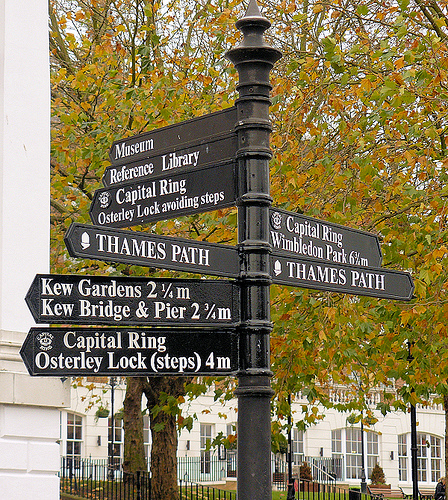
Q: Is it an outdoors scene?
A: Yes, it is outdoors.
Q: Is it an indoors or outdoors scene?
A: It is outdoors.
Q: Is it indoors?
A: No, it is outdoors.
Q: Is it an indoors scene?
A: No, it is outdoors.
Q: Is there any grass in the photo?
A: Yes, there is grass.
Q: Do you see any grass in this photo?
A: Yes, there is grass.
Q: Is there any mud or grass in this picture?
A: Yes, there is grass.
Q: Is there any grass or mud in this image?
A: Yes, there is grass.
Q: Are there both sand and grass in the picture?
A: No, there is grass but no sand.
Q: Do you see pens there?
A: No, there are no pens.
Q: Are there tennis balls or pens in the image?
A: No, there are no pens or tennis balls.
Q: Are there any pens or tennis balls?
A: No, there are no pens or tennis balls.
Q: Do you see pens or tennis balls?
A: No, there are no pens or tennis balls.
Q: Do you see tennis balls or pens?
A: No, there are no pens or tennis balls.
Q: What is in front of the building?
A: The grass is in front of the building.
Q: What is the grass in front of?
A: The grass is in front of the building.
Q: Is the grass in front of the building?
A: Yes, the grass is in front of the building.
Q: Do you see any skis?
A: No, there are no skis.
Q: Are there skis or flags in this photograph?
A: No, there are no skis or flags.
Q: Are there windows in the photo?
A: Yes, there is a window.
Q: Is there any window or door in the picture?
A: Yes, there is a window.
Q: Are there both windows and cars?
A: No, there is a window but no cars.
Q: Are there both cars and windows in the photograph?
A: No, there is a window but no cars.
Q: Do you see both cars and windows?
A: No, there is a window but no cars.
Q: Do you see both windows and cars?
A: No, there is a window but no cars.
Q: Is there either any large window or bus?
A: Yes, there is a large window.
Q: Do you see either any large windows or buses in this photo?
A: Yes, there is a large window.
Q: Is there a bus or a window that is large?
A: Yes, the window is large.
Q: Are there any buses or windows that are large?
A: Yes, the window is large.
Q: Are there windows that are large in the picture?
A: Yes, there is a large window.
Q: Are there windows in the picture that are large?
A: Yes, there is a window that is large.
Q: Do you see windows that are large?
A: Yes, there is a window that is large.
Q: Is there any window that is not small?
A: Yes, there is a large window.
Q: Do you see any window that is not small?
A: Yes, there is a large window.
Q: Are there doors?
A: No, there are no doors.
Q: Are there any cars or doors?
A: No, there are no doors or cars.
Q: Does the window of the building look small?
A: No, the window is large.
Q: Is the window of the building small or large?
A: The window is large.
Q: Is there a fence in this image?
A: Yes, there is a fence.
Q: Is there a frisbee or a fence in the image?
A: Yes, there is a fence.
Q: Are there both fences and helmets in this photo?
A: No, there is a fence but no helmets.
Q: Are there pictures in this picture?
A: No, there are no pictures.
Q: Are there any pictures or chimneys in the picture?
A: No, there are no pictures or chimneys.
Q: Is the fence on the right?
A: Yes, the fence is on the right of the image.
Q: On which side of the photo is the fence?
A: The fence is on the right of the image.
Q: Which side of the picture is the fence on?
A: The fence is on the right of the image.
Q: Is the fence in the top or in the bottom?
A: The fence is in the bottom of the image.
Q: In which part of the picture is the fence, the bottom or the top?
A: The fence is in the bottom of the image.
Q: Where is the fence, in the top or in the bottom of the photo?
A: The fence is in the bottom of the image.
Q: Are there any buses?
A: No, there are no buses.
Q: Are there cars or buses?
A: No, there are no buses or cars.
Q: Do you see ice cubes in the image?
A: No, there are no ice cubes.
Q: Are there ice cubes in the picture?
A: No, there are no ice cubes.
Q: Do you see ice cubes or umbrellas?
A: No, there are no ice cubes or umbrellas.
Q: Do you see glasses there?
A: No, there are no glasses.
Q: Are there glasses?
A: No, there are no glasses.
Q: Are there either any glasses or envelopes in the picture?
A: No, there are no glasses or envelopes.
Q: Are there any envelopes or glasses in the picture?
A: No, there are no glasses or envelopes.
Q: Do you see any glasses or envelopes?
A: No, there are no glasses or envelopes.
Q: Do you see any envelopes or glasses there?
A: No, there are no glasses or envelopes.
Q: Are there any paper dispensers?
A: No, there are no paper dispensers.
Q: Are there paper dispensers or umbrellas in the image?
A: No, there are no paper dispensers or umbrellas.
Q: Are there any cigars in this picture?
A: No, there are no cigars.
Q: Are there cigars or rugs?
A: No, there are no cigars or rugs.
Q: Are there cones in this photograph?
A: No, there are no cones.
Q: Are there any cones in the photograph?
A: No, there are no cones.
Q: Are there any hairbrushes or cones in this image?
A: No, there are no cones or hairbrushes.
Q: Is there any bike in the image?
A: No, there are no bikes.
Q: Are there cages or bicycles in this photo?
A: No, there are no bicycles or cages.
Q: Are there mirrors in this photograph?
A: No, there are no mirrors.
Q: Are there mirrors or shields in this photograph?
A: No, there are no mirrors or shields.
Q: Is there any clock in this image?
A: No, there are no clocks.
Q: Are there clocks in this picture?
A: No, there are no clocks.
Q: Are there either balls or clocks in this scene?
A: No, there are no clocks or balls.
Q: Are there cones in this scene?
A: No, there are no cones.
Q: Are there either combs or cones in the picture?
A: No, there are no cones or combs.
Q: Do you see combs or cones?
A: No, there are no cones or combs.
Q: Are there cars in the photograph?
A: No, there are no cars.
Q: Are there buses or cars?
A: No, there are no cars or buses.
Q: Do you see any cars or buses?
A: No, there are no cars or buses.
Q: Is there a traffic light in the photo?
A: No, there are no traffic lights.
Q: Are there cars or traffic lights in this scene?
A: No, there are no traffic lights or cars.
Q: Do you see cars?
A: No, there are no cars.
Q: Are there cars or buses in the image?
A: No, there are no cars or buses.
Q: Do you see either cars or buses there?
A: No, there are no cars or buses.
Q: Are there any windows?
A: Yes, there is a window.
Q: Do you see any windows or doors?
A: Yes, there is a window.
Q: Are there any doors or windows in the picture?
A: Yes, there is a window.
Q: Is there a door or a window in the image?
A: Yes, there is a window.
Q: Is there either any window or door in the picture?
A: Yes, there is a window.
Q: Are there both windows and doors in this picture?
A: No, there is a window but no doors.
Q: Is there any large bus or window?
A: Yes, there is a large window.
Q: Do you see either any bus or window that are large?
A: Yes, the window is large.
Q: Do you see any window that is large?
A: Yes, there is a large window.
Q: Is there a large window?
A: Yes, there is a large window.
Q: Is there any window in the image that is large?
A: Yes, there is a window that is large.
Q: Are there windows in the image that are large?
A: Yes, there is a window that is large.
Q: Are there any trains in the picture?
A: No, there are no trains.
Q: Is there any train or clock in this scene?
A: No, there are no trains or clocks.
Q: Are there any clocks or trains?
A: No, there are no trains or clocks.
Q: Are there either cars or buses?
A: No, there are no buses or cars.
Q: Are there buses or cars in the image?
A: No, there are no buses or cars.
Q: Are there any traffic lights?
A: No, there are no traffic lights.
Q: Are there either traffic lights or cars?
A: No, there are no traffic lights or cars.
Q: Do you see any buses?
A: No, there are no buses.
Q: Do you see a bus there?
A: No, there are no buses.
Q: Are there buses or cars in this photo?
A: No, there are no buses or cars.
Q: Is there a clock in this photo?
A: No, there are no clocks.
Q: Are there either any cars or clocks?
A: No, there are no clocks or cars.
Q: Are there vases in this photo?
A: No, there are no vases.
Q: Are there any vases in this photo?
A: No, there are no vases.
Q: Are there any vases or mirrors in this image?
A: No, there are no vases or mirrors.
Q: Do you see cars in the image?
A: No, there are no cars.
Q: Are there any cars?
A: No, there are no cars.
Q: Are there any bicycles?
A: No, there are no bicycles.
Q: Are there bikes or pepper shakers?
A: No, there are no bikes or pepper shakers.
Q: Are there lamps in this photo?
A: No, there are no lamps.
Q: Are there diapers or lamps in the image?
A: No, there are no lamps or diapers.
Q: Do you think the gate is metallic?
A: Yes, the gate is metallic.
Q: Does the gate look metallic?
A: Yes, the gate is metallic.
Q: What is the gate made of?
A: The gate is made of metal.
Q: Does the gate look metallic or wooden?
A: The gate is metallic.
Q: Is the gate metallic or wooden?
A: The gate is metallic.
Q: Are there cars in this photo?
A: No, there are no cars.